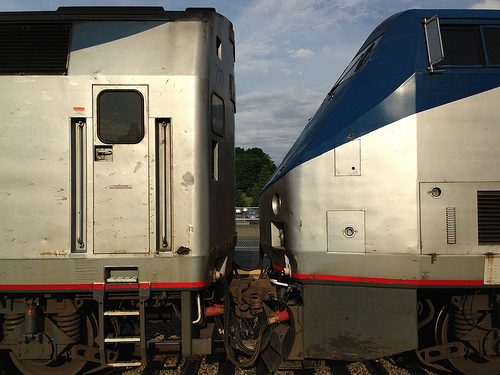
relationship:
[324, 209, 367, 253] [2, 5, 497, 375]
panel on train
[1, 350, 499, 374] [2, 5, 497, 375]
tracks under train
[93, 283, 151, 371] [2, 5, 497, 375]
steps of train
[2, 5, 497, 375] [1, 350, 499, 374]
train on top of tracks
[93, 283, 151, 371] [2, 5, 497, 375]
steps on train